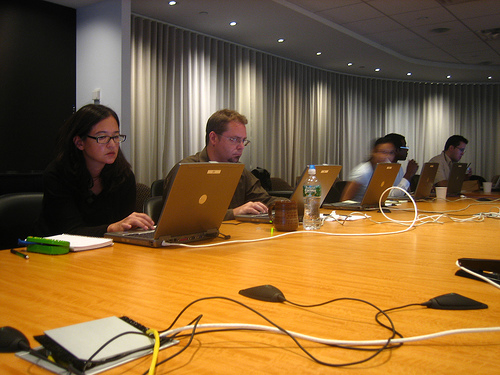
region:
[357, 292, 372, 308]
poart of a wire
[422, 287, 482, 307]
this is a mouse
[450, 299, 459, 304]
the mouse is black in color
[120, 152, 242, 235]
this is a laptop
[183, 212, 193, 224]
the laptop is grey in color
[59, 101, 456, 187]
these are some people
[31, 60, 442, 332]
this is an office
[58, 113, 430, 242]
these people are working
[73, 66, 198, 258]
this is a lady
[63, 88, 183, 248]
the lady is on a laptop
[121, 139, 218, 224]
the laptop is dark gray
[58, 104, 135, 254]
the lady is wearing glasses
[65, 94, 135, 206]
the lady has black hair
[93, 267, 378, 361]
these are cords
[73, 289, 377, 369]
the cords are tangled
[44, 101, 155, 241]
Woman with dark hair and glasses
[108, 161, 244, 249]
Silver laptop on wooden desk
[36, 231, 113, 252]
Notebook next to woman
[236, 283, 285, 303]
Black mouse on desk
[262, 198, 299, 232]
Coffee mug in front of man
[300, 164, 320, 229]
Water bottle in front of man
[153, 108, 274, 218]
Man typing on computer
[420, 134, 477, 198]
Man sitting in back of room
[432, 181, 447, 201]
Coffee cup sitting on desk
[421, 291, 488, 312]
Black computer mouse on desk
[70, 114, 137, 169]
glasses on girl's head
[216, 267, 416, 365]
wires on the table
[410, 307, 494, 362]
white wire on table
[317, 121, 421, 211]
blurry person in photo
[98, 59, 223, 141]
light hitting the blinds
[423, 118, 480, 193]
man at far end of table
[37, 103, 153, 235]
A brown haired woman with glasses and black shirt.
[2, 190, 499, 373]
A long brown wood table.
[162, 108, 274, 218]
A man in glasses sitting at a laptop with water in a bottle in front of him.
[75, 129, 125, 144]
Black glasses on a black shirt woman.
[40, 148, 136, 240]
A black shirt on a woman.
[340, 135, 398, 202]
A black haired blurry woman in white shirt.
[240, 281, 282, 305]
mouse on the table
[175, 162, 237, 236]
a laptop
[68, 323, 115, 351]
a paper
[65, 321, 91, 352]
a white paper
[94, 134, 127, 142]
women wearing glasses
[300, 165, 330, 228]
a water bottle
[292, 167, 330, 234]
water bottle on the table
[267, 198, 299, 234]
the coffee mug is brown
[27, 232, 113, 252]
the notepad is white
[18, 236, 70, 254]
the case for the glasses is green